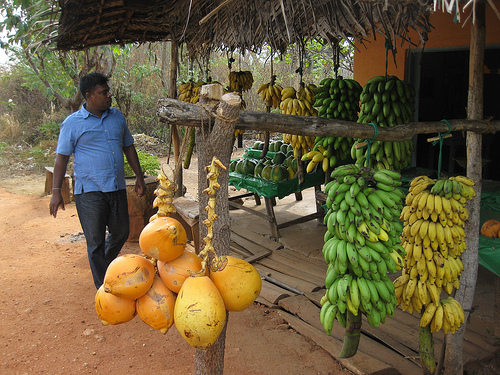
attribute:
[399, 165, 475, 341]
stack — yellow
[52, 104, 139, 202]
shirt — blue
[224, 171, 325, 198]
tarp — green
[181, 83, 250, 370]
tree — cut 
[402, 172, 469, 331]
bananas — yellow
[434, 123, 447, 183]
hook — green 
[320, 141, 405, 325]
bananas — green 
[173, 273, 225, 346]
coconut — yellow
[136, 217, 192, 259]
fruit — big , orange 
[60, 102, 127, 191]
shirt — blue 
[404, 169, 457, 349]
bananas — yellow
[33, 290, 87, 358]
dirt — brown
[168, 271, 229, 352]
fruit — yellow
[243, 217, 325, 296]
floor — wood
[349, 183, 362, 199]
banana — Green 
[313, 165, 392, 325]
bananas — green , bushel 